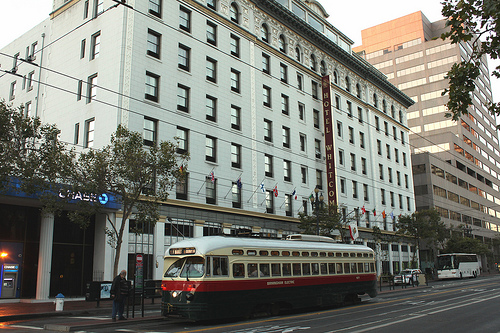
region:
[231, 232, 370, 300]
trolley is red and black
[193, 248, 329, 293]
trolley is white and red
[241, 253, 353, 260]
many windows on bus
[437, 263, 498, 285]
bus is white with tinted windows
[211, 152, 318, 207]
many flags on the building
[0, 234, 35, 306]
atm machine in front of machine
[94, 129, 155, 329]
scrawny tree in front of building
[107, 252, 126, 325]
man standing by trolley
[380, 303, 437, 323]
white lines in street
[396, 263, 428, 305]
white car in front of bus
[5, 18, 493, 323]
A city street scene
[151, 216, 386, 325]
This is a street car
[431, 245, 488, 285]
A bus is parked on the street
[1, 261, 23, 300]
This is an ATM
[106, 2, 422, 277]
A hotel building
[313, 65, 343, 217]
This is the hotel's sign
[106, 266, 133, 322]
A person is standing on the sidewalk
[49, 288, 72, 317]
A fire hydrant is on the sidewalk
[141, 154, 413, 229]
Flags are hanging on the building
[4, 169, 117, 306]
A bank building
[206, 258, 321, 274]
windows on the train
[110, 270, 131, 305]
a person standing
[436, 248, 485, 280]
a white bus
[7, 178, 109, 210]
a chase bank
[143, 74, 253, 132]
windows on the building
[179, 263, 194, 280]
wipers on the train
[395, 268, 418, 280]
a van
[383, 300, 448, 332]
the street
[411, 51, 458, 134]
a brown building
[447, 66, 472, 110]
leaves on the tree are green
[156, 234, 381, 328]
a red white and black trolley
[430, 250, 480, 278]
a black and white bus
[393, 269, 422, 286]
a parked white van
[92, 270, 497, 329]
a paved city street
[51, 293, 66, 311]
a white and blue fire hydrant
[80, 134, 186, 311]
a small green tree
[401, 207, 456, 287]
a small green tree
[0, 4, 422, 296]
a tall white buliding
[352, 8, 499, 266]
a tall brown building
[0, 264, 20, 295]
an ATM machine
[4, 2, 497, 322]
A city landscape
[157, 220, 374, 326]
Bus in the city.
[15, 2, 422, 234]
Large white building.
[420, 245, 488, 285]
Big white tour bus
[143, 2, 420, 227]
Many windows on a white building.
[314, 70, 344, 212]
Hotel sign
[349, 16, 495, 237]
Office building in the city.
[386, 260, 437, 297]
Car in the background.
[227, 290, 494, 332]
Lines on city street.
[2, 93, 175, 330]
Trees and a man on the sidewalk.